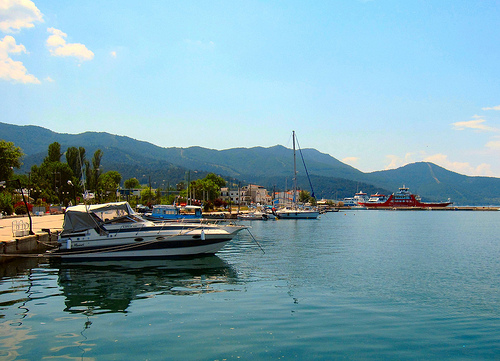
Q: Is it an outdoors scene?
A: Yes, it is outdoors.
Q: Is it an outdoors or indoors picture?
A: It is outdoors.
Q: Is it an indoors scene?
A: No, it is outdoors.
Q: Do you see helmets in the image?
A: No, there are no helmets.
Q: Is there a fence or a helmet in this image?
A: No, there are no helmets or fences.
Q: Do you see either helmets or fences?
A: No, there are no helmets or fences.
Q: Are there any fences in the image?
A: No, there are no fences.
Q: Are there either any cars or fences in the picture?
A: No, there are no fences or cars.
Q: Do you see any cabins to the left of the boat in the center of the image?
A: Yes, there is a cabin to the left of the boat.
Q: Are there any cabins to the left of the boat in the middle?
A: Yes, there is a cabin to the left of the boat.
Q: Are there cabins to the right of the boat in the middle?
A: No, the cabin is to the left of the boat.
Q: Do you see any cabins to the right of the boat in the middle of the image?
A: No, the cabin is to the left of the boat.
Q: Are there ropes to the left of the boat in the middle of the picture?
A: No, there is a cabin to the left of the boat.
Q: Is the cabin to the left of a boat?
A: Yes, the cabin is to the left of a boat.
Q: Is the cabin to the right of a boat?
A: No, the cabin is to the left of a boat.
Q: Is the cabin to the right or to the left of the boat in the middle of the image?
A: The cabin is to the left of the boat.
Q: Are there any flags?
A: No, there are no flags.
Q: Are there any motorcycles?
A: No, there are no motorcycles.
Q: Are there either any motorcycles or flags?
A: No, there are no motorcycles or flags.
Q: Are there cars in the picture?
A: No, there are no cars.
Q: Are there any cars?
A: No, there are no cars.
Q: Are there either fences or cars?
A: No, there are no cars or fences.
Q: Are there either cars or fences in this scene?
A: No, there are no cars or fences.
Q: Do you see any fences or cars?
A: No, there are no cars or fences.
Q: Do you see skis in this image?
A: No, there are no skis.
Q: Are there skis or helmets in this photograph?
A: No, there are no skis or helmets.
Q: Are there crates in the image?
A: No, there are no crates.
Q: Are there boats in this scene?
A: Yes, there is a boat.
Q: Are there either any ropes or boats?
A: Yes, there is a boat.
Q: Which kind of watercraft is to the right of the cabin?
A: The watercraft is a boat.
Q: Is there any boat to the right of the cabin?
A: Yes, there is a boat to the right of the cabin.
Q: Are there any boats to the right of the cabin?
A: Yes, there is a boat to the right of the cabin.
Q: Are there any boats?
A: Yes, there is a boat.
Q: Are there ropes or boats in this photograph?
A: Yes, there is a boat.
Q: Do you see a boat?
A: Yes, there is a boat.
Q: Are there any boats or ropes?
A: Yes, there is a boat.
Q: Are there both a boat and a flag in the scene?
A: No, there is a boat but no flags.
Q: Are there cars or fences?
A: No, there are no cars or fences.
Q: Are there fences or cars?
A: No, there are no cars or fences.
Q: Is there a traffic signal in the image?
A: No, there are no traffic lights.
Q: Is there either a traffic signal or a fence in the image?
A: No, there are no traffic lights or fences.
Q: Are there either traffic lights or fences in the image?
A: No, there are no traffic lights or fences.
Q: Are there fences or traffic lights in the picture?
A: No, there are no traffic lights or fences.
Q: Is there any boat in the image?
A: Yes, there is a boat.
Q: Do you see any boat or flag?
A: Yes, there is a boat.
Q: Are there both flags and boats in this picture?
A: No, there is a boat but no flags.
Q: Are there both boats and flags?
A: No, there is a boat but no flags.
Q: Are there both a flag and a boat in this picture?
A: No, there is a boat but no flags.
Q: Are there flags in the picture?
A: No, there are no flags.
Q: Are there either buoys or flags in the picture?
A: No, there are no flags or buoys.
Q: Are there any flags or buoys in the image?
A: No, there are no flags or buoys.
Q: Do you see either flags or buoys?
A: No, there are no flags or buoys.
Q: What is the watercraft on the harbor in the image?
A: The watercraft is a boat.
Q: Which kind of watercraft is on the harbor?
A: The watercraft is a boat.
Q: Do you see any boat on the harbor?
A: Yes, there is a boat on the harbor.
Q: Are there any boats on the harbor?
A: Yes, there is a boat on the harbor.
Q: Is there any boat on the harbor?
A: Yes, there is a boat on the harbor.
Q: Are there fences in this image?
A: No, there are no fences.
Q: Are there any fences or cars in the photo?
A: No, there are no fences or cars.